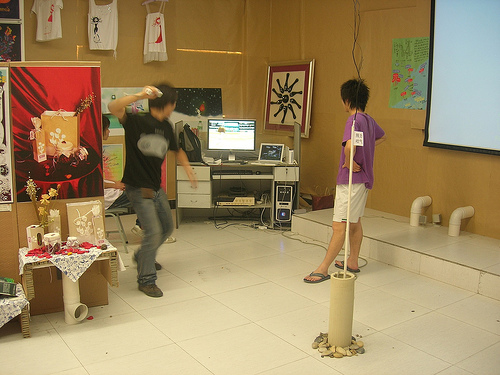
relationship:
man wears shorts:
[299, 77, 393, 288] [327, 183, 373, 226]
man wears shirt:
[299, 77, 393, 288] [334, 111, 387, 191]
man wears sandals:
[299, 77, 393, 288] [293, 257, 363, 290]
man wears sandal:
[299, 77, 393, 288] [332, 256, 362, 276]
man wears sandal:
[299, 77, 393, 288] [301, 266, 334, 287]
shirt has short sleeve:
[334, 111, 387, 191] [336, 121, 361, 147]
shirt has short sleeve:
[334, 111, 387, 191] [373, 115, 386, 141]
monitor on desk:
[200, 117, 259, 165] [171, 145, 304, 234]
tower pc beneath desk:
[274, 182, 294, 226] [171, 145, 304, 234]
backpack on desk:
[177, 118, 215, 167] [171, 145, 304, 234]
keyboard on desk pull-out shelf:
[207, 168, 255, 176] [210, 168, 275, 184]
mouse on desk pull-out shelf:
[253, 168, 261, 175] [210, 168, 275, 184]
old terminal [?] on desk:
[253, 139, 292, 169] [171, 145, 304, 234]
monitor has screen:
[200, 117, 259, 165] [207, 118, 257, 154]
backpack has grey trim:
[177, 118, 215, 167] [179, 127, 196, 154]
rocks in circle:
[310, 325, 368, 364] [325, 331, 357, 353]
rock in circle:
[335, 344, 350, 356] [325, 331, 357, 353]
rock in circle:
[315, 343, 332, 350] [325, 331, 357, 353]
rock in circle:
[356, 345, 366, 355] [325, 331, 357, 353]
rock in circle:
[309, 342, 321, 351] [325, 331, 357, 353]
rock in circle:
[355, 338, 366, 349] [325, 331, 357, 353]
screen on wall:
[418, 1, 499, 156] [248, 0, 499, 248]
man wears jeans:
[106, 77, 202, 304] [123, 179, 177, 283]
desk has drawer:
[171, 145, 304, 234] [175, 164, 213, 184]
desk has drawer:
[171, 145, 304, 234] [176, 180, 212, 197]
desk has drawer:
[171, 145, 304, 234] [177, 193, 214, 210]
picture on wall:
[260, 57, 318, 140] [248, 0, 499, 248]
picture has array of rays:
[260, 57, 318, 140] [269, 71, 304, 125]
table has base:
[19, 232, 124, 346] [54, 262, 93, 328]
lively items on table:
[20, 171, 115, 265] [19, 232, 124, 346]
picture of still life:
[11, 65, 105, 201] [26, 88, 97, 172]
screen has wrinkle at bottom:
[418, 1, 499, 156] [417, 121, 499, 159]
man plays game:
[106, 77, 202, 304] [202, 116, 297, 230]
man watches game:
[299, 77, 393, 288] [202, 116, 297, 230]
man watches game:
[102, 113, 183, 244] [202, 116, 297, 230]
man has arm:
[106, 77, 202, 304] [104, 84, 166, 124]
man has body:
[106, 77, 202, 304] [123, 107, 178, 276]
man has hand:
[299, 77, 393, 288] [336, 155, 365, 177]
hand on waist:
[336, 155, 365, 177] [335, 157, 376, 175]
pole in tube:
[341, 117, 357, 276] [325, 268, 357, 349]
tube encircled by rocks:
[325, 268, 357, 349] [310, 325, 368, 364]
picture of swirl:
[260, 57, 318, 140] [267, 73, 303, 125]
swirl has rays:
[267, 73, 303, 125] [270, 72, 303, 124]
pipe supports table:
[57, 259, 93, 327] [19, 232, 124, 346]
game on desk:
[202, 116, 297, 230] [171, 145, 304, 234]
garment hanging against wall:
[135, 1, 172, 74] [24, 1, 244, 212]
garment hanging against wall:
[80, 0, 124, 63] [24, 1, 244, 212]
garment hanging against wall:
[29, 1, 69, 48] [24, 1, 244, 212]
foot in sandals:
[302, 269, 329, 284] [293, 257, 363, 290]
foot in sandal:
[302, 269, 329, 284] [301, 266, 334, 287]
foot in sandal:
[334, 259, 360, 272] [332, 256, 362, 276]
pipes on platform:
[444, 205, 475, 239] [288, 203, 498, 304]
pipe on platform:
[406, 193, 435, 229] [288, 203, 498, 304]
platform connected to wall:
[288, 203, 498, 304] [248, 0, 499, 248]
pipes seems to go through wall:
[444, 205, 475, 239] [248, 0, 499, 248]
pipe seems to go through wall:
[406, 193, 435, 229] [248, 0, 499, 248]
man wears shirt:
[102, 113, 183, 244] [105, 141, 125, 214]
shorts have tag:
[327, 183, 373, 226] [339, 217, 349, 225]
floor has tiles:
[0, 209, 500, 374] [0, 219, 500, 374]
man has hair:
[299, 77, 393, 288] [338, 75, 375, 114]